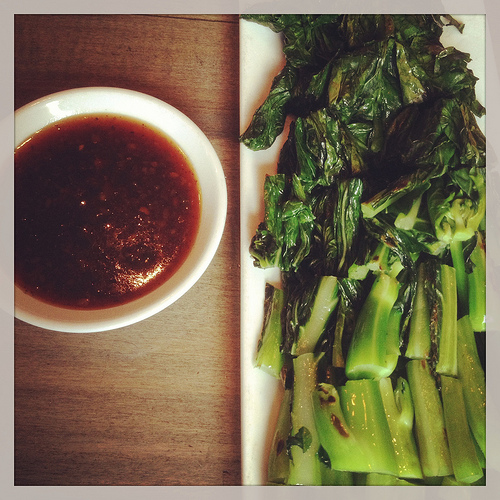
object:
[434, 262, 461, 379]
vegetable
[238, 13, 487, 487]
plate